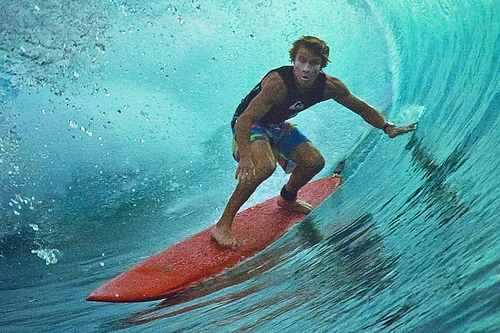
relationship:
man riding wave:
[212, 35, 418, 251] [1, 0, 499, 333]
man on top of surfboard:
[212, 35, 418, 251] [85, 174, 343, 304]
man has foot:
[212, 35, 418, 251] [211, 224, 241, 253]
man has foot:
[212, 35, 418, 251] [277, 196, 314, 214]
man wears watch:
[212, 35, 418, 251] [383, 121, 397, 132]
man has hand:
[212, 35, 418, 251] [390, 121, 419, 139]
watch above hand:
[383, 121, 397, 132] [390, 121, 419, 139]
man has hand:
[212, 35, 418, 251] [234, 153, 257, 186]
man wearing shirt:
[212, 35, 418, 251] [231, 67, 326, 128]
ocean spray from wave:
[1, 0, 258, 265] [1, 0, 499, 333]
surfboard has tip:
[85, 174, 343, 304] [86, 288, 102, 301]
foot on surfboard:
[211, 224, 241, 253] [85, 174, 343, 304]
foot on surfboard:
[277, 196, 314, 214] [85, 174, 343, 304]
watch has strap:
[383, 121, 397, 132] [381, 124, 387, 131]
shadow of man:
[298, 133, 471, 326] [212, 35, 418, 251]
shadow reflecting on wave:
[298, 133, 471, 326] [1, 0, 499, 333]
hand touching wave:
[390, 121, 419, 139] [1, 0, 499, 333]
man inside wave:
[212, 35, 418, 251] [1, 0, 499, 333]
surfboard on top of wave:
[85, 174, 343, 304] [1, 0, 499, 333]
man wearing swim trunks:
[212, 35, 418, 251] [232, 120, 313, 174]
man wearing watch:
[212, 35, 418, 251] [383, 121, 397, 132]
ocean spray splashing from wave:
[1, 0, 258, 265] [1, 0, 499, 333]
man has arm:
[212, 35, 418, 251] [332, 77, 421, 139]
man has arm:
[212, 35, 418, 251] [234, 72, 289, 186]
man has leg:
[212, 35, 418, 251] [271, 122, 326, 215]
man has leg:
[212, 35, 418, 251] [208, 131, 278, 252]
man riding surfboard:
[212, 35, 418, 251] [85, 174, 343, 304]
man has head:
[212, 35, 418, 251] [288, 34, 330, 88]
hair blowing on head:
[289, 34, 332, 68] [288, 34, 330, 88]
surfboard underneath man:
[85, 174, 343, 304] [212, 35, 418, 251]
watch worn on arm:
[383, 121, 397, 132] [332, 77, 421, 139]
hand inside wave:
[390, 121, 419, 139] [1, 0, 499, 333]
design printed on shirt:
[289, 100, 305, 112] [231, 67, 326, 128]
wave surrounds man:
[1, 0, 499, 333] [212, 35, 418, 251]